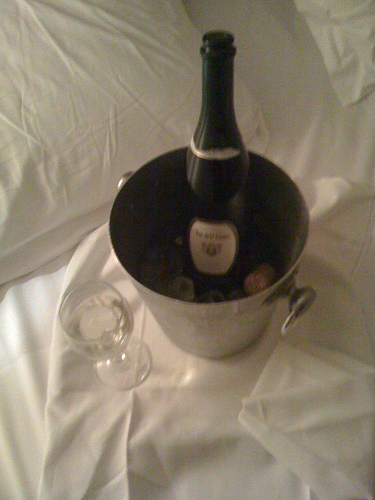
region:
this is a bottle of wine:
[144, 162, 342, 299]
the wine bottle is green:
[189, 230, 246, 296]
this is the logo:
[184, 221, 248, 292]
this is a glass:
[47, 312, 209, 403]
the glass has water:
[71, 319, 135, 375]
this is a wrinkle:
[93, 402, 163, 478]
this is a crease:
[107, 399, 147, 440]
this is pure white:
[104, 441, 129, 469]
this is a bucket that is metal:
[154, 272, 241, 395]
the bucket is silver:
[182, 223, 243, 409]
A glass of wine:
[53, 277, 159, 390]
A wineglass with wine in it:
[54, 274, 151, 390]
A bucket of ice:
[104, 140, 316, 362]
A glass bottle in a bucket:
[109, 28, 317, 367]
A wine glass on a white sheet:
[55, 277, 153, 393]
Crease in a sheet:
[101, 407, 184, 497]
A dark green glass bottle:
[167, 25, 263, 285]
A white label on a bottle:
[186, 215, 244, 279]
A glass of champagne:
[57, 279, 155, 391]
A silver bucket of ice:
[102, 141, 312, 363]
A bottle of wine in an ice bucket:
[94, 10, 337, 365]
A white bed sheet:
[41, 392, 195, 495]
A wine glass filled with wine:
[53, 277, 170, 401]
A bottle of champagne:
[168, 30, 265, 281]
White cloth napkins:
[226, 326, 369, 499]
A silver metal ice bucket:
[102, 134, 351, 369]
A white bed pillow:
[5, 36, 109, 284]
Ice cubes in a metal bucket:
[129, 271, 212, 299]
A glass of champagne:
[49, 271, 170, 401]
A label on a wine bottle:
[174, 207, 252, 284]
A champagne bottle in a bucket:
[159, 24, 280, 292]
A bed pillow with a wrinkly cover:
[5, 101, 103, 265]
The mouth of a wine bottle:
[183, 25, 252, 64]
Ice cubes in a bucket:
[138, 253, 203, 324]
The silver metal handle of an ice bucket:
[266, 276, 334, 347]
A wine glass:
[52, 284, 162, 400]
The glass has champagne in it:
[48, 270, 159, 403]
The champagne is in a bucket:
[102, 19, 333, 381]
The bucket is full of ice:
[121, 175, 297, 321]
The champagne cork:
[237, 258, 279, 291]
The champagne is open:
[193, 18, 236, 51]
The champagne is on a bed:
[59, 38, 338, 349]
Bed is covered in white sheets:
[13, 359, 371, 494]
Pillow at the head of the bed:
[4, 13, 195, 257]